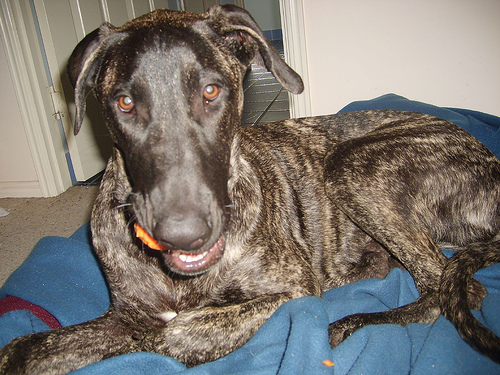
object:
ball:
[132, 221, 168, 253]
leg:
[327, 191, 486, 354]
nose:
[146, 203, 209, 255]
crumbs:
[319, 359, 336, 369]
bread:
[132, 222, 169, 255]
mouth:
[127, 195, 234, 280]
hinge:
[47, 82, 68, 124]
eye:
[111, 91, 137, 114]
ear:
[205, 0, 335, 125]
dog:
[0, 0, 500, 375]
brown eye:
[199, 81, 220, 102]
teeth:
[174, 246, 213, 263]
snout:
[118, 123, 228, 250]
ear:
[64, 22, 115, 134]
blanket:
[244, 288, 405, 367]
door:
[31, 0, 292, 184]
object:
[131, 225, 166, 252]